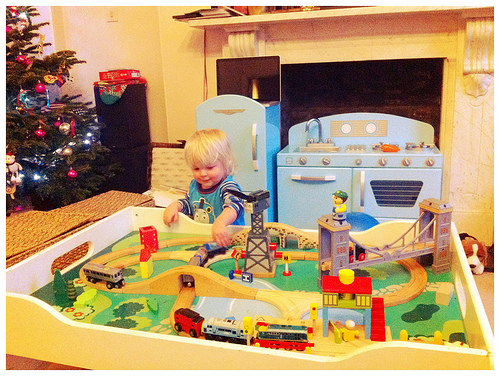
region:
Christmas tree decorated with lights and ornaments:
[7, 9, 67, 189]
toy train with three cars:
[172, 305, 314, 355]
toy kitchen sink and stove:
[276, 113, 439, 200]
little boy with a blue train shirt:
[181, 130, 237, 227]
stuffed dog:
[460, 234, 485, 275]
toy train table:
[101, 209, 476, 366]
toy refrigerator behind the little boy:
[227, 94, 269, 186]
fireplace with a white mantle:
[281, 32, 446, 114]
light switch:
[106, 8, 118, 23]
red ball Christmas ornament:
[63, 168, 78, 178]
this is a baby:
[178, 123, 248, 220]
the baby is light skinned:
[202, 168, 220, 178]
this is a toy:
[172, 306, 195, 331]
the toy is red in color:
[176, 313, 193, 322]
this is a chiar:
[233, 99, 293, 171]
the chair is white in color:
[241, 115, 254, 141]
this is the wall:
[94, 23, 169, 57]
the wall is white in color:
[85, 18, 150, 53]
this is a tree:
[15, 23, 62, 124]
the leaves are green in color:
[78, 135, 99, 184]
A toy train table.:
[33, 208, 482, 362]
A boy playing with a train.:
[170, 130, 244, 251]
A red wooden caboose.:
[162, 303, 205, 333]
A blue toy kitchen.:
[204, 102, 444, 221]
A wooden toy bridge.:
[307, 208, 458, 278]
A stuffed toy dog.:
[458, 233, 489, 278]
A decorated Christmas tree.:
[8, 28, 108, 198]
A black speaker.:
[92, 84, 157, 193]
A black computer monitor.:
[214, 55, 279, 108]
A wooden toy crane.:
[230, 188, 280, 283]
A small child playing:
[33, 88, 490, 374]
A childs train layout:
[52, 197, 482, 367]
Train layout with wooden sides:
[19, 187, 481, 374]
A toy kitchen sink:
[271, 108, 444, 213]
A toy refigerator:
[188, 85, 284, 200]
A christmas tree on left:
[9, 14, 99, 210]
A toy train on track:
[171, 305, 329, 347]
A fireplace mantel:
[191, 10, 496, 50]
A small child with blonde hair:
[165, 108, 245, 224]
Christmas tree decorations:
[17, 33, 78, 170]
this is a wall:
[82, 30, 137, 66]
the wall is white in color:
[83, 25, 148, 57]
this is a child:
[165, 125, 245, 241]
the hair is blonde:
[186, 133, 216, 152]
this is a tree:
[11, 5, 112, 182]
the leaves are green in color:
[11, 64, 26, 79]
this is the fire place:
[276, 44, 451, 116]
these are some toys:
[82, 216, 449, 338]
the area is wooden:
[59, 328, 89, 353]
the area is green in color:
[285, 276, 302, 287]